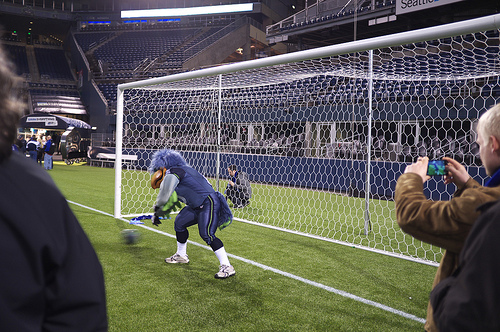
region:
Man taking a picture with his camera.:
[390, 102, 494, 237]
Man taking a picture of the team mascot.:
[397, 105, 495, 212]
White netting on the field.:
[237, 60, 409, 203]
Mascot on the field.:
[133, 107, 256, 274]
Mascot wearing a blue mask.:
[113, 125, 210, 200]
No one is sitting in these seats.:
[105, 28, 206, 73]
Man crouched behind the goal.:
[220, 145, 265, 213]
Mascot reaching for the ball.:
[108, 130, 240, 282]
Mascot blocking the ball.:
[121, 147, 238, 280]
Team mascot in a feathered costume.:
[144, 148, 235, 278]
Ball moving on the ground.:
[116, 222, 143, 249]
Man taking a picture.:
[387, 102, 498, 330]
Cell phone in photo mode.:
[425, 152, 452, 177]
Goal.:
[112, 28, 499, 273]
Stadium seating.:
[1, 2, 498, 201]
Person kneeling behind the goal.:
[220, 159, 255, 210]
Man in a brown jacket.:
[388, 97, 498, 331]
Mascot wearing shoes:
[165, 250, 240, 283]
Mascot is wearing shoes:
[161, 250, 241, 280]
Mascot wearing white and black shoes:
[163, 250, 242, 280]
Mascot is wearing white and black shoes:
[161, 250, 240, 279]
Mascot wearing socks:
[174, 233, 233, 269]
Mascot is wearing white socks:
[172, 235, 235, 268]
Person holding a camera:
[421, 152, 459, 178]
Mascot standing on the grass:
[141, 145, 256, 280]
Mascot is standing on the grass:
[148, 142, 247, 279]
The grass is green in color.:
[124, 281, 242, 327]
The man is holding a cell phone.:
[405, 148, 466, 186]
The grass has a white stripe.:
[255, 247, 372, 320]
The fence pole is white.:
[110, 84, 130, 217]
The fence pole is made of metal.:
[111, 80, 126, 219]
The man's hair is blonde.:
[473, 101, 498, 176]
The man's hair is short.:
[470, 97, 498, 177]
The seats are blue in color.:
[116, 35, 157, 56]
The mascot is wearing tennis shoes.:
[161, 247, 243, 284]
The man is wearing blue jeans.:
[41, 150, 56, 170]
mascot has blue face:
[144, 141, 251, 291]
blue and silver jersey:
[158, 157, 221, 215]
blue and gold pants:
[169, 207, 254, 246]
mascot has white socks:
[177, 232, 237, 265]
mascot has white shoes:
[162, 228, 233, 295]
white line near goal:
[137, 190, 372, 326]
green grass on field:
[217, 216, 299, 330]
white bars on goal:
[97, 45, 250, 237]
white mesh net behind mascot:
[272, 83, 469, 219]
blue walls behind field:
[112, 93, 419, 183]